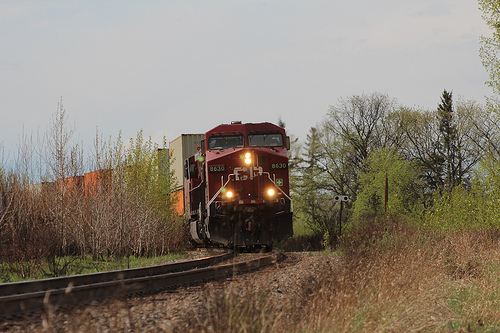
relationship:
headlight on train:
[242, 150, 252, 164] [38, 122, 293, 244]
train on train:
[166, 115, 307, 260] [9, 120, 298, 255]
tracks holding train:
[1, 245, 278, 313] [8, 121, 297, 243]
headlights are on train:
[262, 185, 279, 201] [25, 120, 295, 250]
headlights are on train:
[242, 157, 252, 164] [25, 120, 295, 250]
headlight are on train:
[245, 153, 251, 158] [25, 120, 295, 250]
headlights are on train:
[223, 190, 234, 198] [25, 120, 295, 250]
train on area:
[166, 115, 307, 260] [0, 122, 490, 327]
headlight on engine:
[245, 153, 251, 158] [15, 109, 302, 261]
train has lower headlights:
[166, 115, 307, 260] [212, 173, 328, 221]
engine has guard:
[194, 127, 297, 245] [201, 193, 291, 247]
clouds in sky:
[0, 0, 500, 195] [12, 3, 179, 77]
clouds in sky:
[2, 3, 487, 162] [1, 6, 483, 177]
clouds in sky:
[0, 0, 500, 195] [4, 3, 494, 113]